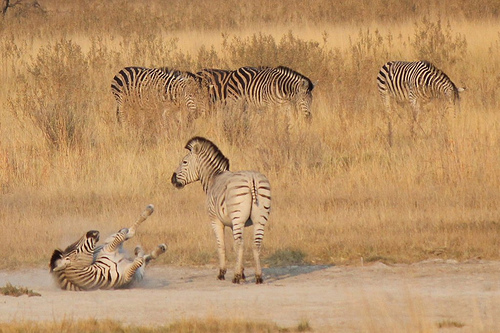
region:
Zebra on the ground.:
[53, 220, 139, 273]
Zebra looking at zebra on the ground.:
[167, 142, 257, 213]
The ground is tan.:
[335, 283, 390, 312]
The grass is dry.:
[36, 162, 85, 201]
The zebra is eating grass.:
[440, 79, 479, 114]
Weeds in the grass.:
[23, 56, 87, 100]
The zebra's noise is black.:
[153, 172, 183, 197]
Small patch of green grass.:
[368, 247, 408, 273]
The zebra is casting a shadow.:
[278, 251, 322, 283]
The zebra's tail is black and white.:
[246, 181, 271, 207]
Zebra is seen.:
[50, 48, 462, 284]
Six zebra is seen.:
[57, 60, 473, 285]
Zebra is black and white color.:
[10, 65, 461, 271]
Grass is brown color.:
[301, 126, 462, 218]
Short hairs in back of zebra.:
[185, 130, 240, 175]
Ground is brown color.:
[300, 280, 415, 310]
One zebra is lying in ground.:
[25, 210, 175, 301]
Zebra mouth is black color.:
[85, 227, 102, 243]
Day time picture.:
[62, 46, 492, 296]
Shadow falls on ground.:
[251, 238, 331, 290]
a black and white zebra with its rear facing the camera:
[161, 130, 309, 283]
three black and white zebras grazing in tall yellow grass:
[97, 40, 331, 131]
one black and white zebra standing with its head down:
[367, 51, 472, 137]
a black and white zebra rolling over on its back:
[38, 188, 169, 302]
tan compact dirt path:
[355, 265, 496, 322]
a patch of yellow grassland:
[357, 150, 495, 248]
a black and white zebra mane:
[182, 134, 242, 167]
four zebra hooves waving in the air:
[108, 198, 183, 271]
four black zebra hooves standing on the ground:
[207, 255, 274, 293]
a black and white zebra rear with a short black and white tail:
[226, 168, 278, 225]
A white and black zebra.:
[172, 134, 274, 284]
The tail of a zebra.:
[242, 182, 260, 232]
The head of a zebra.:
[171, 138, 226, 189]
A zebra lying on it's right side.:
[50, 208, 168, 292]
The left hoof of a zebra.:
[140, 202, 161, 223]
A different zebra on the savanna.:
[380, 57, 461, 148]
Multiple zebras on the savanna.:
[111, 64, 316, 108]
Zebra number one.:
[201, 67, 315, 124]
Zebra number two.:
[112, 64, 199, 102]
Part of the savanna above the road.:
[1, 2, 498, 257]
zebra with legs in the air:
[42, 195, 179, 303]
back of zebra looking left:
[167, 128, 281, 286]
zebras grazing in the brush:
[93, 60, 328, 130]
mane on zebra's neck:
[200, 134, 230, 158]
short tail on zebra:
[244, 168, 263, 212]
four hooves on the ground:
[211, 263, 281, 287]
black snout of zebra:
[82, 228, 104, 245]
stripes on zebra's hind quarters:
[220, 182, 248, 219]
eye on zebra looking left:
[175, 156, 197, 171]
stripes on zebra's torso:
[384, 65, 422, 86]